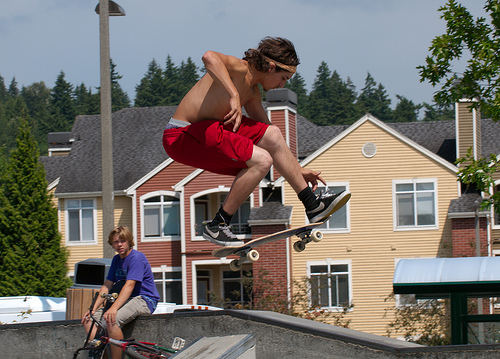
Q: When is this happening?
A: Daytime.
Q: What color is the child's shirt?
A: Purple.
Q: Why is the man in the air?
A: Skateboard trick.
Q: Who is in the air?
A: Skateboarder.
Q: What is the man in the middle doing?
A: Skateboarding.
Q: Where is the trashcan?
A: Behind child.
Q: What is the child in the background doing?
A: Resting.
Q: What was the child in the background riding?
A: Bicycle.